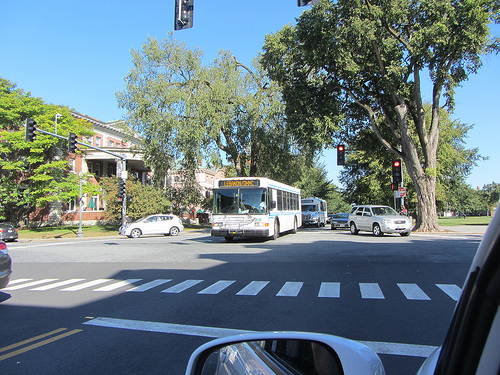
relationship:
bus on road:
[195, 166, 320, 256] [177, 232, 427, 325]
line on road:
[150, 269, 255, 301] [177, 232, 427, 325]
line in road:
[150, 269, 255, 301] [177, 232, 427, 325]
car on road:
[119, 206, 196, 254] [177, 232, 427, 325]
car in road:
[119, 206, 196, 254] [177, 232, 427, 325]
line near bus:
[150, 269, 255, 301] [195, 166, 320, 256]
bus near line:
[195, 166, 320, 256] [150, 269, 255, 301]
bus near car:
[195, 166, 320, 256] [119, 206, 196, 254]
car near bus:
[119, 206, 196, 254] [195, 166, 320, 256]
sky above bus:
[35, 2, 133, 103] [195, 166, 320, 256]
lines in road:
[13, 270, 466, 306] [7, 224, 490, 374]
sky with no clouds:
[0, 2, 500, 192] [2, 4, 498, 199]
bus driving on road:
[195, 166, 320, 256] [7, 229, 489, 372]